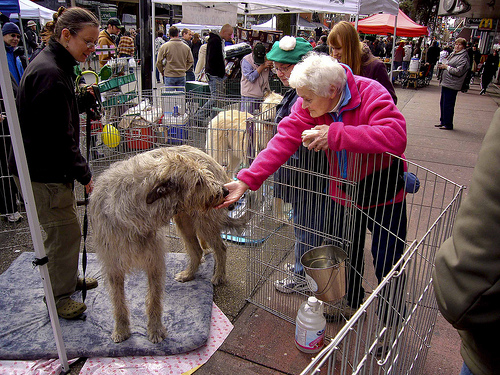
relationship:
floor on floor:
[1, 303, 241, 373] [1, 65, 496, 372]